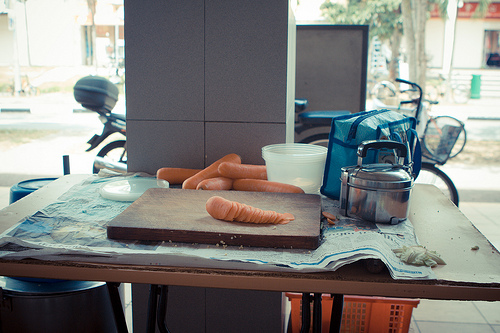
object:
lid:
[100, 175, 169, 200]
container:
[259, 142, 327, 194]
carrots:
[155, 152, 303, 193]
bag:
[320, 107, 423, 199]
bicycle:
[393, 79, 466, 209]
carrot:
[206, 194, 293, 225]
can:
[468, 75, 480, 100]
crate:
[287, 292, 424, 331]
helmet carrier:
[71, 75, 118, 116]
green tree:
[314, 3, 399, 21]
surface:
[0, 174, 500, 301]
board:
[107, 187, 323, 248]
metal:
[371, 190, 405, 216]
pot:
[339, 141, 414, 226]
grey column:
[124, 1, 286, 175]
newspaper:
[431, 124, 465, 164]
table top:
[1, 172, 500, 288]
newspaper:
[2, 169, 439, 281]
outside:
[2, 2, 500, 333]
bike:
[73, 75, 128, 173]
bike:
[293, 98, 352, 146]